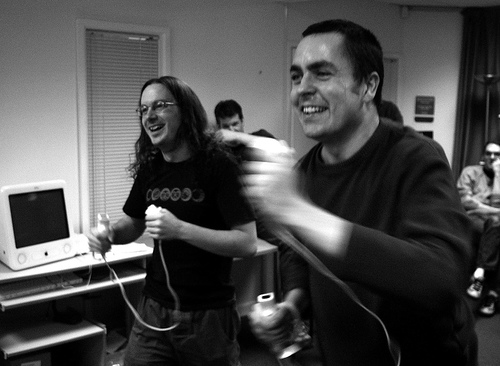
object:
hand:
[241, 146, 292, 217]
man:
[219, 18, 478, 366]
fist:
[142, 207, 171, 238]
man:
[86, 72, 257, 365]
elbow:
[403, 237, 464, 304]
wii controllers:
[215, 127, 296, 157]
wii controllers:
[144, 205, 164, 216]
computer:
[0, 179, 76, 271]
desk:
[1, 241, 154, 366]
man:
[456, 143, 498, 316]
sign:
[414, 95, 435, 116]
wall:
[405, 9, 467, 178]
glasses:
[136, 101, 180, 115]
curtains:
[450, 14, 500, 178]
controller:
[221, 130, 290, 172]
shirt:
[286, 116, 477, 366]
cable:
[266, 221, 401, 365]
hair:
[298, 19, 387, 109]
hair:
[126, 77, 230, 176]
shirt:
[121, 151, 250, 314]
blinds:
[88, 28, 160, 226]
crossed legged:
[466, 221, 500, 315]